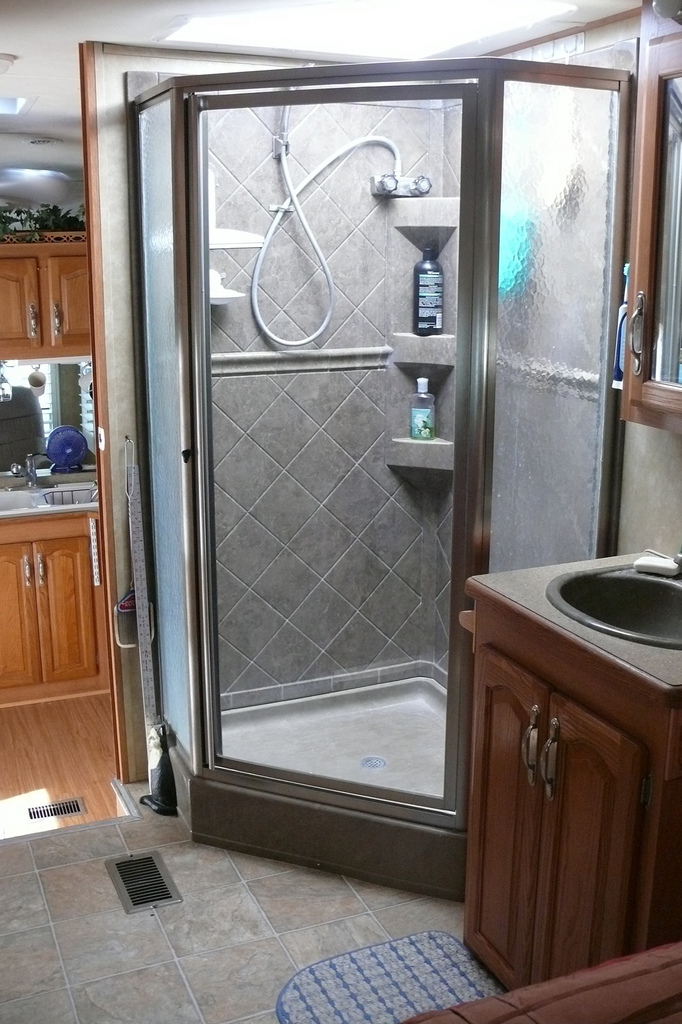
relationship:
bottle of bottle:
[413, 244, 443, 335] [413, 244, 443, 335]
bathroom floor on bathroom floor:
[0, 688, 510, 1024] [9, 827, 348, 1020]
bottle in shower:
[413, 246, 443, 332] [113, 46, 646, 908]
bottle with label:
[406, 373, 433, 439] [406, 410, 433, 439]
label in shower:
[406, 410, 433, 439] [113, 46, 646, 908]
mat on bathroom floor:
[276, 931, 507, 1019] [0, 688, 510, 1024]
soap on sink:
[632, 554, 680, 575] [470, 546, 679, 678]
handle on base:
[523, 704, 542, 787] [459, 551, 682, 991]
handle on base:
[540, 717, 558, 800] [459, 551, 682, 991]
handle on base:
[542, 704, 558, 801] [459, 551, 682, 991]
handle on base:
[519, 704, 540, 787] [459, 551, 682, 991]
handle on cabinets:
[37, 555, 45, 586] [0, 510, 97, 686]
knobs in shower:
[368, 170, 431, 196] [113, 46, 646, 908]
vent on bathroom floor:
[108, 854, 175, 915] [0, 688, 510, 1024]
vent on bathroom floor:
[20, 799, 91, 820] [0, 688, 510, 1024]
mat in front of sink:
[275, 933, 503, 1019] [470, 546, 679, 678]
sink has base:
[470, 546, 679, 678] [458, 591, 674, 978]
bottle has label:
[409, 378, 435, 441] [408, 404, 435, 438]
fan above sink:
[46, 427, 84, 472] [0, 483, 99, 513]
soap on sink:
[634, 558, 680, 578] [470, 546, 679, 678]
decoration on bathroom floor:
[139, 725, 178, 815] [0, 688, 510, 1024]